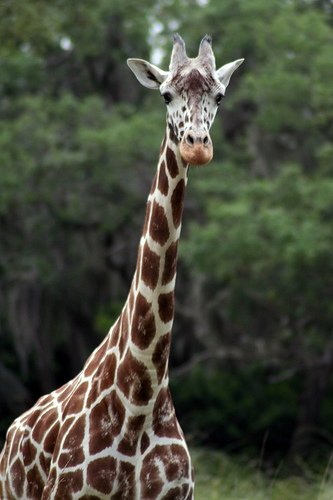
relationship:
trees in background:
[13, 19, 249, 317] [8, 12, 327, 417]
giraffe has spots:
[11, 55, 209, 496] [54, 420, 191, 489]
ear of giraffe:
[131, 62, 165, 90] [11, 55, 209, 496]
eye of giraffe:
[162, 90, 176, 109] [11, 55, 209, 496]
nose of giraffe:
[186, 125, 211, 161] [11, 55, 209, 496]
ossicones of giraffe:
[164, 31, 217, 63] [11, 55, 209, 496]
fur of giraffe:
[155, 206, 180, 240] [11, 55, 209, 496]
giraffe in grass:
[11, 55, 209, 496] [196, 454, 317, 492]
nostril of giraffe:
[202, 134, 210, 149] [11, 55, 209, 496]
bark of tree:
[194, 303, 234, 365] [127, 25, 330, 283]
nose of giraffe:
[185, 127, 210, 152] [11, 55, 209, 496]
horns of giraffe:
[152, 42, 215, 65] [11, 55, 209, 496]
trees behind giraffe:
[13, 19, 249, 317] [11, 55, 209, 496]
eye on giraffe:
[162, 90, 176, 109] [11, 55, 209, 496]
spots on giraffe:
[54, 420, 191, 489] [11, 55, 209, 496]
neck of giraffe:
[129, 156, 170, 339] [11, 55, 209, 496]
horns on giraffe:
[152, 42, 215, 65] [11, 55, 209, 496]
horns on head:
[152, 42, 215, 65] [173, 69, 221, 142]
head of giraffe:
[173, 69, 221, 142] [11, 55, 209, 496]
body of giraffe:
[25, 364, 184, 497] [11, 55, 209, 496]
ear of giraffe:
[208, 53, 248, 87] [11, 55, 209, 496]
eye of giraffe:
[206, 84, 238, 111] [11, 55, 209, 496]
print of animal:
[79, 351, 129, 460] [14, 41, 256, 499]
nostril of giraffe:
[203, 127, 210, 152] [11, 55, 209, 496]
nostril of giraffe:
[186, 119, 195, 148] [11, 55, 209, 496]